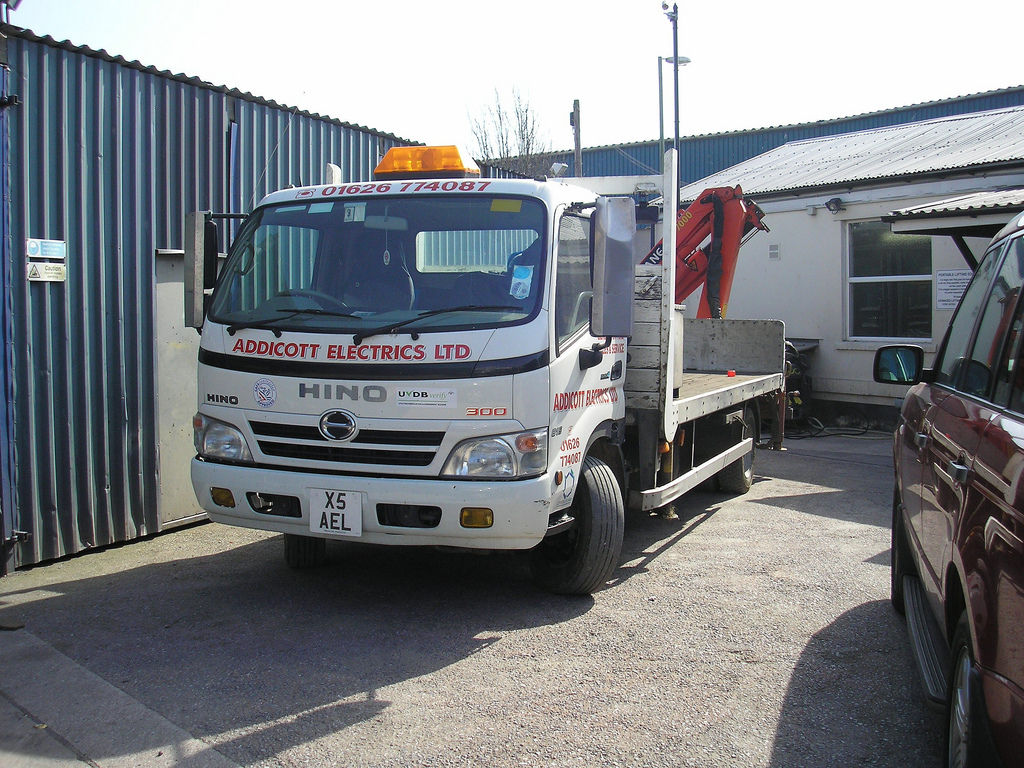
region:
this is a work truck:
[114, 63, 947, 765]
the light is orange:
[359, 136, 467, 223]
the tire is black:
[523, 487, 713, 627]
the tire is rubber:
[476, 435, 692, 610]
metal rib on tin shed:
[16, 33, 42, 562]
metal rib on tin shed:
[33, 39, 60, 562]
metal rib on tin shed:
[52, 46, 82, 552]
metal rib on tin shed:
[74, 58, 98, 548]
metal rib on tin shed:
[89, 52, 113, 544]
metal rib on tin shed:
[106, 58, 135, 542]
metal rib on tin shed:
[160, 74, 173, 251]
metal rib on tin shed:
[172, 80, 185, 248]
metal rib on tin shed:
[185, 79, 201, 210]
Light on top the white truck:
[334, 124, 541, 197]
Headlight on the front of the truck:
[166, 400, 556, 499]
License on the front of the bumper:
[270, 473, 379, 569]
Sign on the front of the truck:
[228, 325, 478, 380]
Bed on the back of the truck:
[557, 173, 818, 554]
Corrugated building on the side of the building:
[23, 37, 463, 620]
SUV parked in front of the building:
[854, 177, 1022, 751]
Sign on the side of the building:
[13, 220, 96, 328]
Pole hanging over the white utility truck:
[623, 4, 715, 186]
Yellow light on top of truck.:
[349, 121, 515, 230]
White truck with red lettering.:
[124, 122, 687, 625]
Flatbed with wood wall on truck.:
[528, 129, 801, 547]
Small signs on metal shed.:
[8, 194, 104, 356]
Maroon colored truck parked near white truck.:
[833, 181, 1018, 754]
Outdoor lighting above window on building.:
[789, 175, 885, 251]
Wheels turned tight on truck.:
[131, 374, 654, 637]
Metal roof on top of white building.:
[691, 91, 1021, 199]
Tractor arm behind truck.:
[626, 172, 776, 350]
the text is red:
[218, 322, 487, 376]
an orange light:
[373, 121, 490, 183]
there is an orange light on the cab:
[350, 124, 509, 185]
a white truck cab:
[151, 116, 731, 708]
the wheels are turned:
[223, 459, 720, 653]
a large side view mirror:
[591, 171, 664, 367]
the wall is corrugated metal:
[12, 26, 518, 618]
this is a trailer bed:
[623, 171, 813, 548]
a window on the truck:
[532, 206, 619, 355]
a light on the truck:
[342, 118, 523, 223]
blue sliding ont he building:
[49, 104, 189, 343]